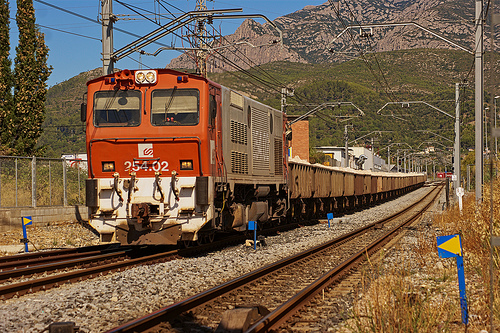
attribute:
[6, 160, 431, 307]
tracks — rust colored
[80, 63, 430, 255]
train — orange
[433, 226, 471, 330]
sign — blue, yellow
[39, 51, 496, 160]
grass — green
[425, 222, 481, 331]
yellow sign — blue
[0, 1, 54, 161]
green trees — yellow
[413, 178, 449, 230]
edge of a rail — on ground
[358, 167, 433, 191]
edge of a train — on ground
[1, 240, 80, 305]
edge of a rail — on ground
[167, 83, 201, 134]
part of a window — on the train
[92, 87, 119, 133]
part of a window — on the train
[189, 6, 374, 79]
rocky mountain — behind train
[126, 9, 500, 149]
covered hill top — behind train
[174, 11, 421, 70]
brown bushes — behind train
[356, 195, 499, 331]
grass and weeds — behind train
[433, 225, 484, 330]
yellow flag sign — behind train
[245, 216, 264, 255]
blue flag sign — behind train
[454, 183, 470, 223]
white paddle sign — behind train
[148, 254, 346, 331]
empty railroad track — behind train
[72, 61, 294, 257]
train engine — on train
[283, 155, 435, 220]
cargo train cars — on train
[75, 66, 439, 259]
powered train — on train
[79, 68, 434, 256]
long train — on train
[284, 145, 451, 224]
brown box cars — on train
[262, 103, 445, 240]
tracks side by side — on train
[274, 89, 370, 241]
short signal pole — behind train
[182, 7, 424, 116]
wires and supports — behind train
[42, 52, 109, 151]
steep mountain — behind train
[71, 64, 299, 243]
engine car — behind train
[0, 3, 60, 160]
skinny trees — behind train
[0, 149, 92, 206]
chainlink fence — behind train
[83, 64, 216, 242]
front of the train — burnt orange